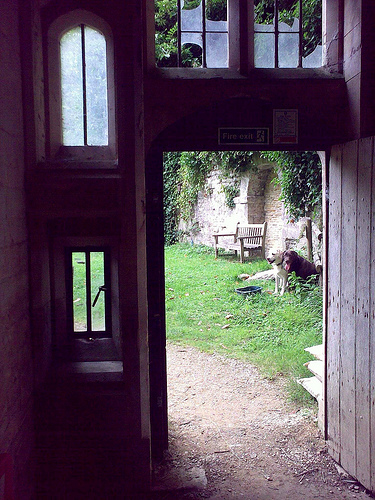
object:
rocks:
[172, 465, 208, 494]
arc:
[246, 164, 285, 253]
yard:
[166, 239, 326, 345]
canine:
[265, 249, 288, 296]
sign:
[216, 128, 265, 144]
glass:
[180, 0, 227, 68]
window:
[154, 1, 328, 69]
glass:
[250, 18, 322, 70]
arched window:
[46, 6, 118, 162]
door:
[325, 135, 374, 498]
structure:
[327, 137, 374, 494]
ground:
[321, 112, 340, 137]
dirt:
[166, 338, 371, 498]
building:
[1, 0, 374, 498]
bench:
[212, 221, 268, 265]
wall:
[165, 53, 227, 87]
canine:
[282, 249, 317, 283]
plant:
[161, 148, 324, 254]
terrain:
[166, 245, 324, 374]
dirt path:
[176, 339, 277, 424]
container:
[236, 285, 263, 296]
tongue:
[285, 264, 290, 270]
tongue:
[268, 262, 271, 264]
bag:
[303, 338, 323, 363]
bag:
[302, 356, 328, 382]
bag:
[293, 370, 322, 400]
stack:
[295, 339, 324, 406]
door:
[162, 138, 330, 450]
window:
[68, 245, 113, 339]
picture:
[255, 128, 266, 143]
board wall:
[325, 137, 375, 497]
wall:
[167, 149, 327, 274]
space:
[171, 247, 315, 365]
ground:
[167, 372, 327, 496]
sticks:
[294, 462, 319, 480]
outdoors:
[163, 150, 324, 391]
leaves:
[217, 309, 240, 330]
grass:
[58, 241, 328, 402]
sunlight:
[58, 27, 106, 147]